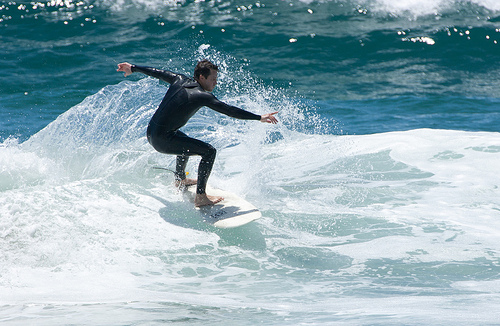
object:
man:
[111, 55, 279, 206]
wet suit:
[128, 66, 264, 193]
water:
[367, 120, 408, 152]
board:
[174, 180, 264, 231]